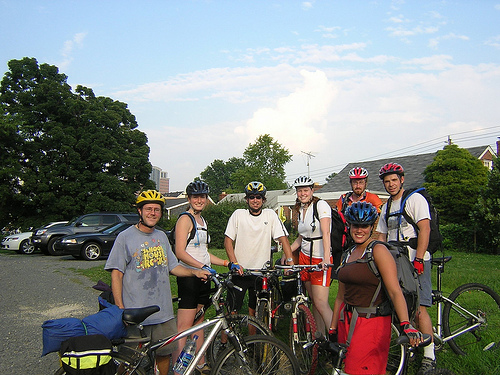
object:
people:
[334, 167, 381, 272]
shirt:
[334, 191, 383, 245]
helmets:
[135, 187, 168, 204]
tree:
[421, 144, 490, 222]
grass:
[75, 248, 500, 373]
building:
[313, 144, 499, 204]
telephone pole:
[307, 155, 309, 176]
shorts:
[295, 250, 332, 286]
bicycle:
[92, 270, 280, 375]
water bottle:
[174, 334, 199, 373]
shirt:
[295, 199, 334, 258]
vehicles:
[60, 221, 137, 259]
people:
[102, 188, 213, 375]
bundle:
[42, 303, 128, 354]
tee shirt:
[225, 207, 291, 270]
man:
[372, 162, 442, 373]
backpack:
[402, 187, 440, 252]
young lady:
[327, 199, 422, 375]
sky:
[0, 0, 499, 194]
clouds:
[385, 26, 409, 39]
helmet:
[185, 179, 211, 193]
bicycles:
[52, 273, 301, 373]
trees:
[0, 57, 155, 233]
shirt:
[103, 225, 189, 327]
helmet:
[341, 200, 379, 223]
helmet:
[292, 174, 314, 189]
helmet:
[377, 161, 406, 176]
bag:
[63, 334, 117, 374]